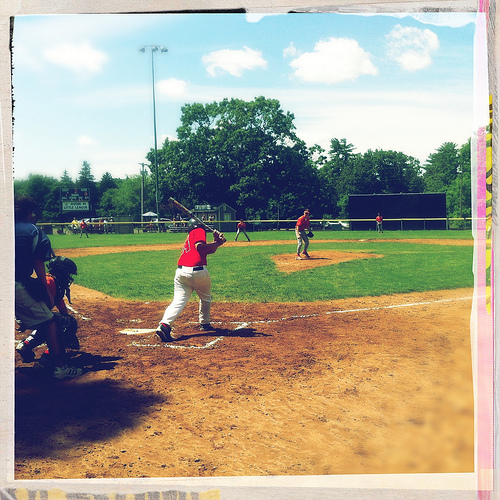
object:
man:
[155, 216, 228, 342]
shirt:
[176, 227, 207, 267]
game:
[14, 196, 471, 381]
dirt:
[14, 239, 475, 480]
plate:
[118, 328, 156, 336]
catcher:
[15, 256, 80, 367]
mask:
[47, 256, 78, 290]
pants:
[159, 265, 212, 326]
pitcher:
[294, 209, 315, 261]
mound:
[269, 250, 385, 274]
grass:
[44, 229, 491, 304]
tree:
[144, 95, 310, 226]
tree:
[95, 187, 141, 217]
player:
[234, 218, 251, 242]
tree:
[418, 142, 460, 193]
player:
[375, 211, 385, 234]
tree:
[75, 159, 100, 205]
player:
[78, 218, 90, 239]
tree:
[334, 158, 382, 197]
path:
[65, 295, 473, 350]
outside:
[12, 12, 476, 479]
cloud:
[200, 45, 268, 79]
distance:
[13, 12, 473, 260]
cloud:
[288, 37, 378, 84]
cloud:
[382, 23, 439, 72]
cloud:
[154, 77, 190, 100]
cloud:
[44, 40, 108, 76]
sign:
[59, 187, 93, 235]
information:
[60, 187, 91, 211]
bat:
[167, 196, 227, 244]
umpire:
[15, 194, 83, 380]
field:
[14, 217, 473, 480]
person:
[70, 217, 80, 229]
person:
[103, 216, 110, 234]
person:
[98, 218, 105, 230]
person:
[208, 211, 216, 225]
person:
[200, 214, 208, 222]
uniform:
[159, 227, 212, 329]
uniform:
[23, 255, 78, 355]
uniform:
[294, 215, 310, 254]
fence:
[35, 217, 471, 235]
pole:
[137, 44, 168, 233]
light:
[138, 47, 146, 55]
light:
[150, 46, 160, 54]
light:
[160, 47, 168, 53]